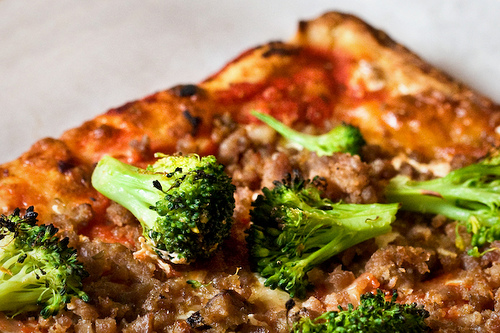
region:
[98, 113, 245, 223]
green broccoli on pizza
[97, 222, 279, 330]
brown meat on pizza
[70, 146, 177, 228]
green stems on broccoli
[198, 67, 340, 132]
red sauce on pizza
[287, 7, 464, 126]
brown crust on pizza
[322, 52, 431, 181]
yellow cheese on pizza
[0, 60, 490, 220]
pizza on white plate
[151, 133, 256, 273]
dark green florets of broccoli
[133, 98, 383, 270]
brown sausage on pizza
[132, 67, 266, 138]
black char spots on pizza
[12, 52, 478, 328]
this is the pizza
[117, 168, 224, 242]
this is the brocolli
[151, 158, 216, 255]
the brocolli is green in colour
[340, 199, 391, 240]
this is the stem of the brocolli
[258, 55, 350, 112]
this is the sauce in the pizza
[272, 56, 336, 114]
the sauce is red in colour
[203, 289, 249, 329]
this is courgette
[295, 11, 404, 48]
this is the edge of the pizza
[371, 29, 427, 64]
this is the crust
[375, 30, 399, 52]
the crust is black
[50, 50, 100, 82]
this is a plate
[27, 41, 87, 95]
the plate is clean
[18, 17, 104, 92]
the plate is white in color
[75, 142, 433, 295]
this is some broccolli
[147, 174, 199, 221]
the broccolli is green in color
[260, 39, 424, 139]
this is a pizza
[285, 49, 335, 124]
the pizza is red in color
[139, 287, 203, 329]
this is some meat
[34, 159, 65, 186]
the area is brown in color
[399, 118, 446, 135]
the area is oily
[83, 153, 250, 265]
a piece of broccolo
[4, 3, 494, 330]
broccoli on pizza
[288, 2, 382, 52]
corner of the pizza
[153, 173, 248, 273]
top of the broccoli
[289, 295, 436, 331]
head of the broccoli is dark green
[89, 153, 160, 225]
stem of the broccoli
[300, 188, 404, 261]
light green stem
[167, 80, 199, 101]
black spot on the crust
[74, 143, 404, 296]
two pieces of broccoli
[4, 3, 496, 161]
crust around the edge of the pizza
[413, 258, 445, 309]
part f a food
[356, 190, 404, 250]
part of a stalk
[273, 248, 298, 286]
part of a stalk